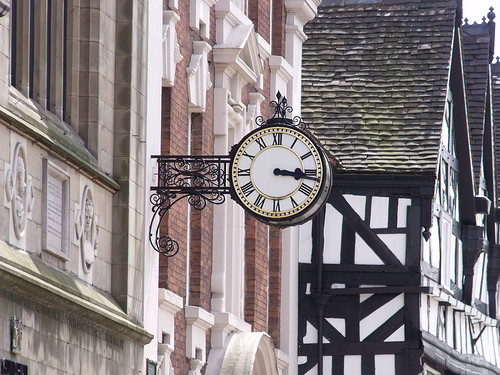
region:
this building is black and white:
[306, 4, 493, 371]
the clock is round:
[207, 83, 362, 235]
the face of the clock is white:
[218, 92, 345, 236]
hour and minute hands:
[265, 163, 336, 188]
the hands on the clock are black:
[221, 109, 363, 240]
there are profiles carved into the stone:
[8, 139, 117, 283]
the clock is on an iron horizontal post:
[134, 78, 366, 301]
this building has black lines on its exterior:
[325, 137, 480, 374]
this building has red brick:
[167, 1, 309, 374]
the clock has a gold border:
[201, 82, 343, 238]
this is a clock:
[108, 67, 429, 292]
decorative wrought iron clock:
[99, 70, 343, 275]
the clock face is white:
[188, 78, 414, 291]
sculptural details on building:
[11, 137, 144, 287]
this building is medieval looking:
[334, 93, 491, 367]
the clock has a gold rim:
[174, 72, 373, 224]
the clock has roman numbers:
[205, 57, 401, 264]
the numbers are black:
[229, 57, 384, 246]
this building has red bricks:
[189, 216, 286, 286]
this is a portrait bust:
[55, 180, 115, 267]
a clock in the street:
[226, 118, 338, 232]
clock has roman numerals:
[224, 115, 338, 232]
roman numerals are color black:
[226, 116, 341, 232]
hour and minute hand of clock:
[271, 164, 316, 184]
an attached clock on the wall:
[142, 87, 340, 263]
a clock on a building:
[5, 0, 341, 367]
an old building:
[300, 0, 487, 371]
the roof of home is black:
[306, 0, 478, 174]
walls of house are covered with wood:
[298, 172, 472, 372]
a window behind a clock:
[209, 13, 259, 318]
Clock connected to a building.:
[148, 118, 338, 223]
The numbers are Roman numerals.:
[233, 130, 321, 213]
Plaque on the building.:
[41, 162, 76, 268]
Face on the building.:
[66, 181, 108, 271]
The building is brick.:
[175, 6, 271, 360]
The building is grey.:
[2, 128, 142, 373]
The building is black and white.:
[308, 186, 482, 373]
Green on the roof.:
[344, 89, 416, 174]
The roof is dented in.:
[293, 45, 440, 168]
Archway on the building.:
[213, 329, 293, 373]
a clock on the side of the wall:
[154, 120, 330, 250]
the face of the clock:
[231, 123, 330, 224]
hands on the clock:
[270, 163, 320, 181]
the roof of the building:
[311, 26, 429, 171]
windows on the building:
[8, 15, 83, 122]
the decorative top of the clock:
[259, 91, 306, 124]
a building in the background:
[317, 8, 489, 358]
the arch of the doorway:
[217, 330, 274, 370]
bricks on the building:
[165, 225, 190, 303]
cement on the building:
[86, 20, 140, 371]